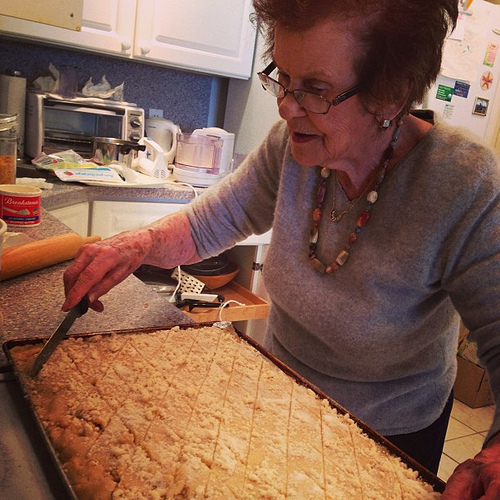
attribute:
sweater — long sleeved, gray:
[185, 107, 497, 436]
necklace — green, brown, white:
[307, 112, 409, 274]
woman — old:
[62, 1, 496, 498]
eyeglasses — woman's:
[255, 57, 375, 114]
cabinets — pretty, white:
[138, 4, 255, 92]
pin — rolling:
[1, 204, 118, 337]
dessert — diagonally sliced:
[15, 341, 423, 498]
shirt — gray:
[180, 131, 487, 429]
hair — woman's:
[242, 0, 464, 122]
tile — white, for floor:
[463, 412, 480, 440]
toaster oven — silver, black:
[22, 79, 162, 171]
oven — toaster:
[23, 91, 148, 163]